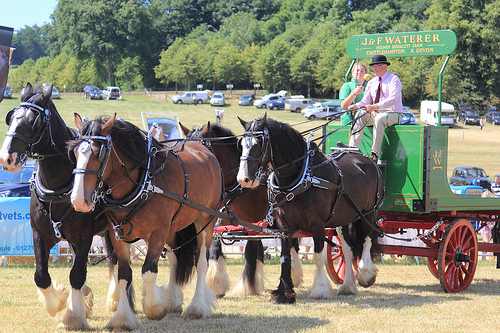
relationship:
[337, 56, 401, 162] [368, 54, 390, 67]
man has a hat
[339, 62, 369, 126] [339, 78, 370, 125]
woman has shirt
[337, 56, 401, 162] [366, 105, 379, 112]
man has hand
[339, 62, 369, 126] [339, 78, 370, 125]
person has shirt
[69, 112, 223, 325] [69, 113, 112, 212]
horse has head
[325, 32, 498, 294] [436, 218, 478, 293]
wagon has wheel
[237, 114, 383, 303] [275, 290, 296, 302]
horse has hoof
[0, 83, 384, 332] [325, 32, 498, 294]
horses pull wagon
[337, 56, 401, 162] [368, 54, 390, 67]
person wears hat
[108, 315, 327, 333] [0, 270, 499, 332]
shadow on ground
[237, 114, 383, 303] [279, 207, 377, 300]
horse has legs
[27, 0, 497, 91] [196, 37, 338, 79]
trees have leaves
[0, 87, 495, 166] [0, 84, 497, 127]
field has cars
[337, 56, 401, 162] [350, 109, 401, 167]
person wears pants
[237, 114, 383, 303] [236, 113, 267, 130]
horse has ears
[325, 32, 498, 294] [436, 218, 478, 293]
carriage has wheel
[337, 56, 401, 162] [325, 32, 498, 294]
person on carriage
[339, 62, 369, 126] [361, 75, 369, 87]
person holding microphone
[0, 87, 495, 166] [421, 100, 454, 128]
field has camper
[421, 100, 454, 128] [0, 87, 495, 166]
camper on field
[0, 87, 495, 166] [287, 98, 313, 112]
field has van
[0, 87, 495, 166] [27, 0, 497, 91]
field has trees